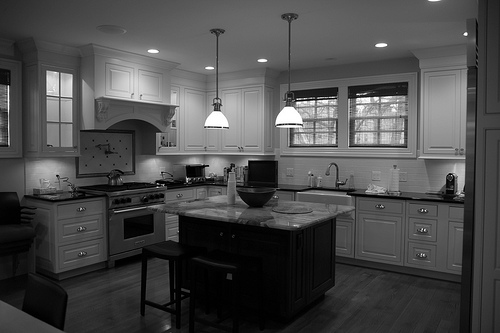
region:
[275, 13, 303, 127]
a hanging pendant light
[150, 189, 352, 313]
a marble topped kitchen island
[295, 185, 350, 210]
a white farmhouse kitchen sink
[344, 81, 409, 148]
a window in a kitchen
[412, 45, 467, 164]
an overhead kitchen cupboard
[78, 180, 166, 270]
a silver kitchen range and stove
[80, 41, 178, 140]
an overhead stove fan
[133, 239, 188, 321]
a kitchen stool at an island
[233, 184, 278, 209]
a bowl on a kitchen island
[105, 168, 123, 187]
a silver kettle on a stove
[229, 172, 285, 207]
a bowl on the counter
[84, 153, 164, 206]
kettle on the stove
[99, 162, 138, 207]
kettle on the stove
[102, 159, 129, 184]
kettle on the stove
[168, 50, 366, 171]
two lights are on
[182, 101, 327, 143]
two lights are on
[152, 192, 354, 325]
A kitchen island.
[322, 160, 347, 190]
Kitchen sink fixtures.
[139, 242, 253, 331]
Bar stools.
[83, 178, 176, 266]
A stainless steel oven and stovetop.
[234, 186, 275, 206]
A large dark colored bowl.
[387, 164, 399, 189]
A roll of paper towels.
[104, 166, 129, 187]
A silver tea kettle on the stove.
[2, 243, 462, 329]
Hardwood floors.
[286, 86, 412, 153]
The kitchen window.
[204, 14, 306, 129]
Hanging lights.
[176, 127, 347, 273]
a bowl on a counter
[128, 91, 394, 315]
a bowl on an island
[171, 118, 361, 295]
a counter with a bowl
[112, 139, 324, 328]
an island with a bowl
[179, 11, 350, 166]
two hanging lights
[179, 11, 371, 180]
two hanging lights turned on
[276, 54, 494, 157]
two windows side by side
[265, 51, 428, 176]
side by side windows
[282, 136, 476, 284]
a sink on counters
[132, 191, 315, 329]
chairs under a bar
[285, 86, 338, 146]
glass window next to window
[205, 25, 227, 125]
light hanging from ceiling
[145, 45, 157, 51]
round white light in ceiling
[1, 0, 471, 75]
white painted ceiling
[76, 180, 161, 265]
stainless steel stove next to cabinet with drawers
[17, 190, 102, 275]
white cabinet with drawers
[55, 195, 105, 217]
top white drawer next to stove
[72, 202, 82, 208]
silver knob on drawer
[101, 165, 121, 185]
stainless steel kettle on stove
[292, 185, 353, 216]
white sink under windows